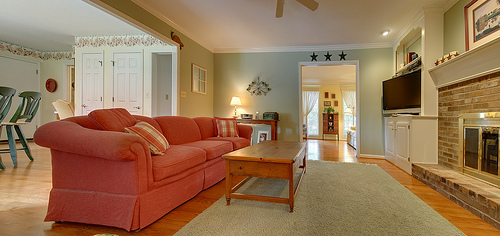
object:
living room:
[0, 0, 500, 236]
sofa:
[32, 108, 254, 233]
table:
[221, 140, 308, 213]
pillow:
[124, 121, 171, 155]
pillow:
[216, 119, 241, 138]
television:
[381, 68, 423, 115]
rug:
[167, 159, 472, 236]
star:
[338, 50, 347, 60]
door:
[301, 64, 358, 157]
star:
[324, 51, 333, 61]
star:
[310, 52, 318, 62]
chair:
[0, 88, 18, 170]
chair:
[0, 90, 43, 166]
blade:
[275, 0, 285, 19]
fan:
[271, 0, 320, 20]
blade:
[294, 0, 321, 12]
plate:
[45, 78, 56, 92]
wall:
[38, 51, 73, 129]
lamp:
[230, 97, 243, 118]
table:
[236, 118, 281, 141]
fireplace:
[436, 71, 500, 189]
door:
[457, 112, 500, 188]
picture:
[463, 0, 500, 52]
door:
[112, 52, 143, 116]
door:
[81, 53, 104, 116]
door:
[0, 57, 39, 140]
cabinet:
[382, 116, 437, 175]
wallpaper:
[0, 34, 174, 62]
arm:
[32, 120, 141, 162]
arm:
[237, 124, 253, 139]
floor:
[0, 140, 500, 236]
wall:
[213, 45, 395, 158]